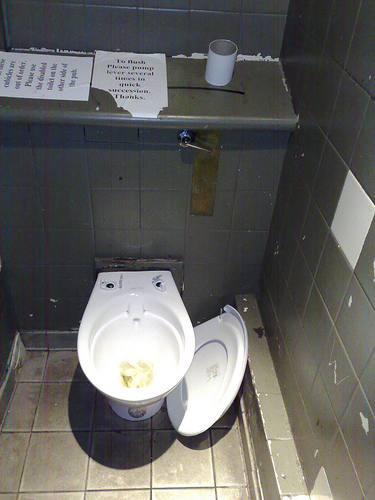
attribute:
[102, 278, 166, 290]
lid — broken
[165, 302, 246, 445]
toilet seat — white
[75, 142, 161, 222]
wall — grey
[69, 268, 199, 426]
toilet — white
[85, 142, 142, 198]
tile — gray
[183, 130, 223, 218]
board — brown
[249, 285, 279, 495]
ledge — gray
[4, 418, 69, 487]
floor — tiled